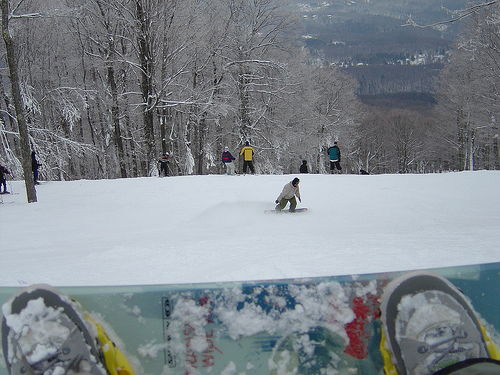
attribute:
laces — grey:
[4, 282, 488, 370]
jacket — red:
[226, 149, 234, 166]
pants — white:
[223, 160, 238, 175]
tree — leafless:
[2, 0, 39, 203]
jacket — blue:
[326, 145, 341, 160]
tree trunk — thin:
[0, 1, 42, 205]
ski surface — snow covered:
[2, 169, 484, 287]